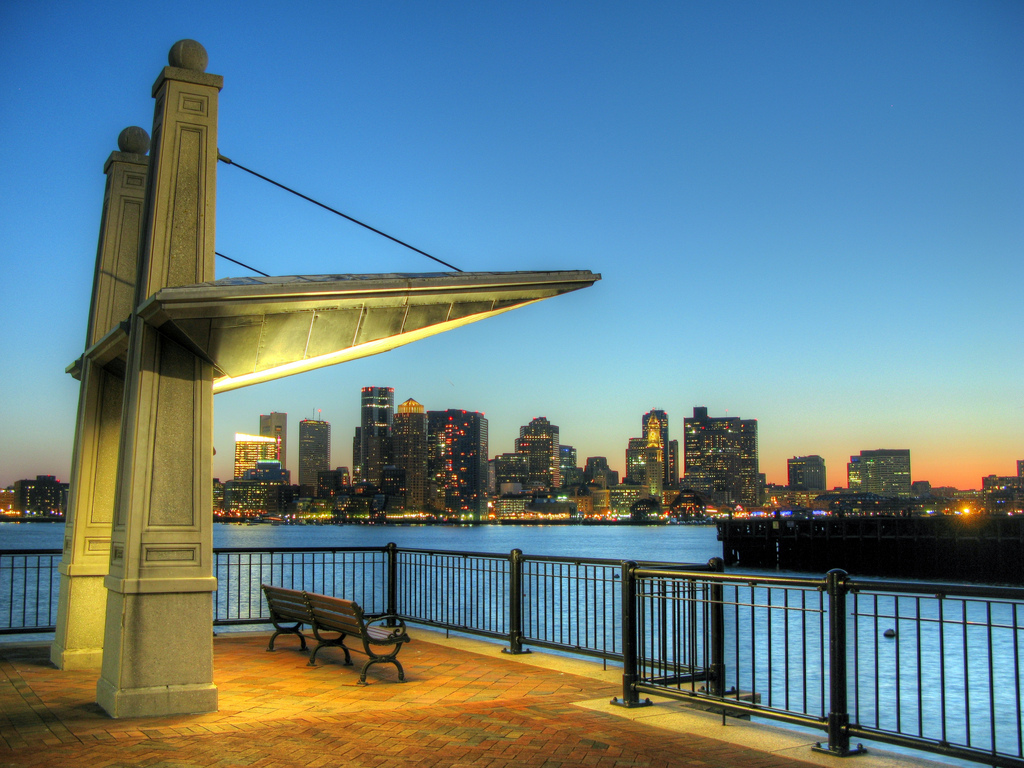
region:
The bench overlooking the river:
[266, 575, 394, 680]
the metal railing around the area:
[3, 520, 987, 732]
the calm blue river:
[10, 507, 987, 732]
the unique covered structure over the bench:
[112, 141, 587, 712]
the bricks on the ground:
[17, 637, 823, 765]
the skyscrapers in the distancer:
[48, 391, 997, 544]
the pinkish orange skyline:
[30, 422, 1010, 511]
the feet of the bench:
[260, 628, 415, 682]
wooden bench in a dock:
[256, 579, 409, 675]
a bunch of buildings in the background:
[231, 384, 928, 521]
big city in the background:
[1, 367, 1020, 523]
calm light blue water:
[16, 521, 1019, 760]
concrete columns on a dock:
[54, 29, 223, 729]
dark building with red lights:
[425, 405, 492, 519]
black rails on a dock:
[1, 544, 1019, 764]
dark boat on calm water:
[718, 504, 1019, 581]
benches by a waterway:
[253, 575, 427, 690]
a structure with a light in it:
[42, 31, 611, 730]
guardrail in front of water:
[2, 525, 1012, 759]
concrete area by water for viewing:
[8, 588, 888, 759]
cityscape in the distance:
[0, 363, 1007, 538]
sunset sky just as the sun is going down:
[0, 12, 1022, 519]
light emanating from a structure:
[207, 279, 593, 404]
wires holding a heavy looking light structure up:
[206, 148, 475, 289]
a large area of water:
[7, 499, 1016, 750]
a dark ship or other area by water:
[708, 481, 1022, 584]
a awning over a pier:
[167, 252, 602, 386]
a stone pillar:
[91, 37, 228, 717]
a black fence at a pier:
[0, 542, 1021, 765]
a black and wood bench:
[259, 583, 406, 688]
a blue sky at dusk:
[2, 1, 1021, 498]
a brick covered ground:
[0, 628, 823, 764]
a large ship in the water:
[700, 504, 1021, 587]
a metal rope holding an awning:
[216, 153, 464, 280]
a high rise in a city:
[643, 407, 667, 464]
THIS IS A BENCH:
[245, 563, 420, 691]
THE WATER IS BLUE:
[0, 531, 1019, 765]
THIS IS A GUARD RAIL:
[0, 531, 1019, 763]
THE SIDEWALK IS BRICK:
[10, 621, 858, 762]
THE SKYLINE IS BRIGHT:
[35, 381, 1019, 555]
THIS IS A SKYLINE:
[4, 386, 985, 551]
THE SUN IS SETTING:
[781, 433, 1019, 501]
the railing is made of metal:
[3, 543, 1018, 765]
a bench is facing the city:
[259, 582, 405, 678]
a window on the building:
[537, 426, 544, 465]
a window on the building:
[484, 410, 492, 458]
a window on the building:
[445, 391, 461, 462]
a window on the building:
[379, 435, 396, 454]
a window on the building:
[401, 413, 412, 449]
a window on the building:
[533, 448, 571, 493]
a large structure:
[48, 39, 611, 728]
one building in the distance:
[440, 401, 492, 522]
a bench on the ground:
[253, 570, 424, 695]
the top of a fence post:
[819, 562, 852, 592]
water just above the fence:
[536, 527, 699, 556]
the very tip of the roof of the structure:
[561, 252, 613, 307]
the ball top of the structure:
[159, 29, 211, 80]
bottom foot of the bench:
[346, 676, 375, 690]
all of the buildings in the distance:
[7, 385, 1020, 518]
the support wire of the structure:
[206, 142, 494, 275]